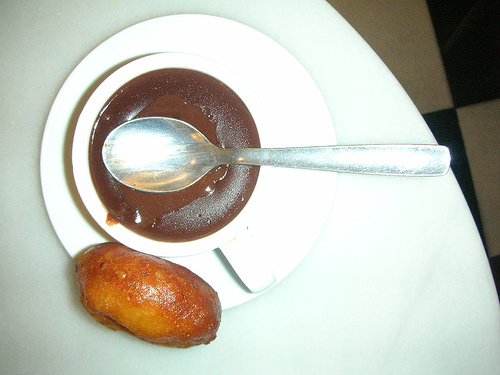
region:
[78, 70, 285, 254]
sauce in bowl is brown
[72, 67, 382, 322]
sauce in bowl is brown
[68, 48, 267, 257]
The bowl of pudding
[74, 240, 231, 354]
The brown pastry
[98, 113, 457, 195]
The silver spoon in the pudding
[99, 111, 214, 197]
The bowl of the spoon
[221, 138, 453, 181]
The handle of the spoon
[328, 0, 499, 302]
The black and white checkered floor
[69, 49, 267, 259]
The bowl the pudding is in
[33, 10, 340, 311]
The plate the bowl is on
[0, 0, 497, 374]
The table the plate is on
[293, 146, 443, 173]
The reflection on the spoon handle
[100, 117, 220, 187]
Spoon on a chocolate cake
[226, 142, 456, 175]
Handle of a metal spoon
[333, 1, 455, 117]
White tile on a floor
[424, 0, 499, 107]
Black tile on a floor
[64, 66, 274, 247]
Chocolate cake on a white plate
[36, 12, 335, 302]
White plate under a white plate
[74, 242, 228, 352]
Donut on the side of a white plate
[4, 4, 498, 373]
Round white table with plates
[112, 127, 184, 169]
Reflection of light on a spoon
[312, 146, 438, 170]
Light reflection on a spoon's handle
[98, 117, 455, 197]
a metal spoon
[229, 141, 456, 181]
the handle of a metal spoon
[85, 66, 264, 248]
brown sauce on the plate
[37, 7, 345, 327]
a white plate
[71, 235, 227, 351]
a brown pastry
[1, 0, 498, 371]
a white table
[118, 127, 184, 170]
light shining on the spoon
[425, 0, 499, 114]
a black tile on the floor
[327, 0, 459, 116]
a white tile on the floor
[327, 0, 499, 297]
a black and white tiled floor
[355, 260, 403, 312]
the tablecloth is white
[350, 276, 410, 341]
the tablecloth is white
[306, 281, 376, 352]
the tablecloth is white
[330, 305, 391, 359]
the tablecloth is white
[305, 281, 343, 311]
the tablecloth is white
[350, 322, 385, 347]
the tablecloth is white